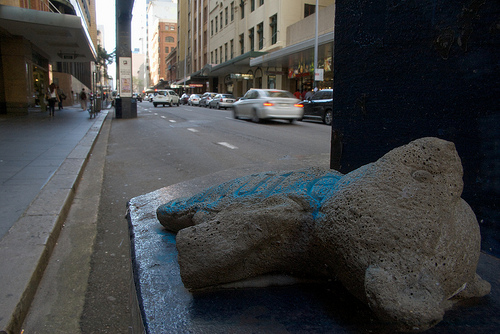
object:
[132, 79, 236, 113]
background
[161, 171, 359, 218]
paint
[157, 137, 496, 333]
rock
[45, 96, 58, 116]
people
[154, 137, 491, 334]
bear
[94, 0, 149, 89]
sky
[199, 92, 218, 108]
car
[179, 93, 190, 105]
car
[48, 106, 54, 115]
pants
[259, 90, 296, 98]
back window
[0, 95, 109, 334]
sidewalk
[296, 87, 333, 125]
car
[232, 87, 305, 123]
car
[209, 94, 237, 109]
car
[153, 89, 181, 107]
car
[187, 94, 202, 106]
car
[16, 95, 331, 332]
road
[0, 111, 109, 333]
curb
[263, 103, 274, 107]
light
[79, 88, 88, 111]
people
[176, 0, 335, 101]
building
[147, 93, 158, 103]
vehicle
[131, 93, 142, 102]
vehicle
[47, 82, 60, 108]
person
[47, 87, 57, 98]
shirt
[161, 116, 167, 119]
line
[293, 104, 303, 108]
taillights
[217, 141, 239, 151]
lines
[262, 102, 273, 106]
taillights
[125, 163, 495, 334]
platform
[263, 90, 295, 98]
window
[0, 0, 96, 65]
overhang